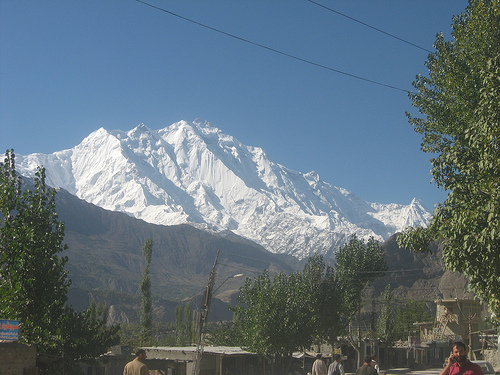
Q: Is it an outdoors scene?
A: Yes, it is outdoors.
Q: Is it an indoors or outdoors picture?
A: It is outdoors.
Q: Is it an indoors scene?
A: No, it is outdoors.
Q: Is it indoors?
A: No, it is outdoors.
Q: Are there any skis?
A: No, there are no skis.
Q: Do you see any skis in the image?
A: No, there are no skis.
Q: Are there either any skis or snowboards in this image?
A: No, there are no skis or snowboards.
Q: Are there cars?
A: No, there are no cars.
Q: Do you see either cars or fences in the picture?
A: No, there are no cars or fences.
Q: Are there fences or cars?
A: No, there are no cars or fences.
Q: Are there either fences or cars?
A: No, there are no cars or fences.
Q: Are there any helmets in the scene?
A: No, there are no helmets.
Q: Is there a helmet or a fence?
A: No, there are no helmets or fences.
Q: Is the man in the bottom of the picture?
A: Yes, the man is in the bottom of the image.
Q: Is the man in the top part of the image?
A: No, the man is in the bottom of the image.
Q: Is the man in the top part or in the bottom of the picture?
A: The man is in the bottom of the image.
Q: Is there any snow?
A: Yes, there is snow.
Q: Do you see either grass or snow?
A: Yes, there is snow.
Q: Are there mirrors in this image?
A: No, there are no mirrors.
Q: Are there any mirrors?
A: No, there are no mirrors.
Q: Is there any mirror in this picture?
A: No, there are no mirrors.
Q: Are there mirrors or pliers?
A: No, there are no mirrors or pliers.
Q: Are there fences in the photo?
A: No, there are no fences.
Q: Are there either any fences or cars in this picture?
A: No, there are no fences or cars.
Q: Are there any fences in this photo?
A: No, there are no fences.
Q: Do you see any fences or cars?
A: No, there are no fences or cars.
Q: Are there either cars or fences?
A: No, there are no fences or cars.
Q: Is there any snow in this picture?
A: Yes, there is snow.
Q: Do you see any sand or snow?
A: Yes, there is snow.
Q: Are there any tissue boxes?
A: No, there are no tissue boxes.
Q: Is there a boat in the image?
A: No, there are no boats.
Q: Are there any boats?
A: No, there are no boats.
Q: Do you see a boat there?
A: No, there are no boats.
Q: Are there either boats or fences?
A: No, there are no boats or fences.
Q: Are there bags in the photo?
A: No, there are no bags.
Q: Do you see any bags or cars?
A: No, there are no bags or cars.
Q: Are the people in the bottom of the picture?
A: Yes, the people are in the bottom of the image.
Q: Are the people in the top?
A: No, the people are in the bottom of the image.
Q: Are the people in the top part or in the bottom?
A: The people are in the bottom of the image.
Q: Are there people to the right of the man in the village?
A: Yes, there are people to the right of the man.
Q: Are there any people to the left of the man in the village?
A: No, the people are to the right of the man.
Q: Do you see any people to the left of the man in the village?
A: No, the people are to the right of the man.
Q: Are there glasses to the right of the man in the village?
A: No, there are people to the right of the man.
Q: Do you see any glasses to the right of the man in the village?
A: No, there are people to the right of the man.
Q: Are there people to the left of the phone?
A: Yes, there are people to the left of the phone.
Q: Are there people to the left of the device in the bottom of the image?
A: Yes, there are people to the left of the phone.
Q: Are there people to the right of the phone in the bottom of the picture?
A: No, the people are to the left of the telephone.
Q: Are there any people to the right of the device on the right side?
A: No, the people are to the left of the telephone.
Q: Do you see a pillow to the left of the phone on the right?
A: No, there are people to the left of the phone.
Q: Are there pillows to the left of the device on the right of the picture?
A: No, there are people to the left of the phone.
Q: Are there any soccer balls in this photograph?
A: No, there are no soccer balls.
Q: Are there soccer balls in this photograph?
A: No, there are no soccer balls.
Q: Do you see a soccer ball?
A: No, there are no soccer balls.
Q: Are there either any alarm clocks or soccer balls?
A: No, there are no soccer balls or alarm clocks.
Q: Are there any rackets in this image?
A: No, there are no rackets.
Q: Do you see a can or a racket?
A: No, there are no rackets or cans.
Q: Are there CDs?
A: No, there are no cds.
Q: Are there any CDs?
A: No, there are no cds.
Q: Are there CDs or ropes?
A: No, there are no CDs or ropes.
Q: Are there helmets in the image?
A: No, there are no helmets.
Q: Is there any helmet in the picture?
A: No, there are no helmets.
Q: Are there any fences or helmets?
A: No, there are no helmets or fences.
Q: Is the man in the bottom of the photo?
A: Yes, the man is in the bottom of the image.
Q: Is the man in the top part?
A: No, the man is in the bottom of the image.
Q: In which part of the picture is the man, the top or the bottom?
A: The man is in the bottom of the image.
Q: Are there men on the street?
A: Yes, there is a man on the street.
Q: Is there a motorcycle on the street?
A: No, there is a man on the street.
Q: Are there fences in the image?
A: No, there are no fences.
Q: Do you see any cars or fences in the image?
A: No, there are no fences or cars.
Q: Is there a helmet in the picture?
A: No, there are no helmets.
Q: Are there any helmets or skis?
A: No, there are no helmets or skis.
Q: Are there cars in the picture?
A: No, there are no cars.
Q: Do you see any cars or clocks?
A: No, there are no cars or clocks.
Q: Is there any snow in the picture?
A: Yes, there is snow.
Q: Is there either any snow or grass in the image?
A: Yes, there is snow.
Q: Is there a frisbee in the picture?
A: No, there are no frisbees.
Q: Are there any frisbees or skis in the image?
A: No, there are no frisbees or skis.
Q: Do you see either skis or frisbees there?
A: No, there are no frisbees or skis.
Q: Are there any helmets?
A: No, there are no helmets.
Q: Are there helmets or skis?
A: No, there are no helmets or skis.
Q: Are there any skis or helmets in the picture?
A: No, there are no helmets or skis.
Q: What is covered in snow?
A: The mountain is covered in snow.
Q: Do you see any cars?
A: No, there are no cars.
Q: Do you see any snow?
A: Yes, there is snow.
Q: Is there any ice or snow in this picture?
A: Yes, there is snow.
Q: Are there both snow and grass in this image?
A: No, there is snow but no grass.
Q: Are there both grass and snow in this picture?
A: No, there is snow but no grass.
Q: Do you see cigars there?
A: No, there are no cigars.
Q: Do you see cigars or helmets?
A: No, there are no cigars or helmets.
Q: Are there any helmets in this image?
A: No, there are no helmets.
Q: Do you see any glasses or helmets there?
A: No, there are no helmets or glasses.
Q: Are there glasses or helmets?
A: No, there are no helmets or glasses.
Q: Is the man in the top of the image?
A: No, the man is in the bottom of the image.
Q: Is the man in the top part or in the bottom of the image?
A: The man is in the bottom of the image.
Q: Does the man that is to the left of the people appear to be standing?
A: Yes, the man is standing.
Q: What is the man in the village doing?
A: The man is standing.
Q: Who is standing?
A: The man is standing.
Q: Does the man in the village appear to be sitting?
A: No, the man is standing.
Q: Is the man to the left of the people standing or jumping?
A: The man is standing.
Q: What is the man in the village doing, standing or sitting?
A: The man is standing.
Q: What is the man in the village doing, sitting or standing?
A: The man is standing.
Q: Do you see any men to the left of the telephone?
A: Yes, there is a man to the left of the telephone.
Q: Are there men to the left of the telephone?
A: Yes, there is a man to the left of the telephone.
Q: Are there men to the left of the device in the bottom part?
A: Yes, there is a man to the left of the telephone.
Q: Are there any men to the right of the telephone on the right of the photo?
A: No, the man is to the left of the telephone.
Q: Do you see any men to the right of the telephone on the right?
A: No, the man is to the left of the telephone.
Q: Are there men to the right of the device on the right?
A: No, the man is to the left of the telephone.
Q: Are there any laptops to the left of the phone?
A: No, there is a man to the left of the phone.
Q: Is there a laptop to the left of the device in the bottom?
A: No, there is a man to the left of the phone.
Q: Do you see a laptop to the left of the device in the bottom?
A: No, there is a man to the left of the phone.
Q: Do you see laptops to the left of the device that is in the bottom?
A: No, there is a man to the left of the phone.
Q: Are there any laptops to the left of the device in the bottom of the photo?
A: No, there is a man to the left of the phone.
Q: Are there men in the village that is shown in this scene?
A: Yes, there is a man in the village.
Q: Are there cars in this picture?
A: No, there are no cars.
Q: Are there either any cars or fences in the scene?
A: No, there are no cars or fences.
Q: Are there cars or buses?
A: No, there are no cars or buses.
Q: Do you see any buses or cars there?
A: No, there are no cars or buses.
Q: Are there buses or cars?
A: No, there are no cars or buses.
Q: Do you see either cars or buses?
A: No, there are no cars or buses.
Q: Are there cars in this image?
A: No, there are no cars.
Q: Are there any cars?
A: No, there are no cars.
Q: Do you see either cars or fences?
A: No, there are no cars or fences.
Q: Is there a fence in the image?
A: No, there are no fences.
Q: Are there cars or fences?
A: No, there are no fences or cars.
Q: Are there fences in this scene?
A: No, there are no fences.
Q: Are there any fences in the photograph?
A: No, there are no fences.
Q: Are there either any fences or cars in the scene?
A: No, there are no fences or cars.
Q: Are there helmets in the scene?
A: No, there are no helmets.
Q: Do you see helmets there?
A: No, there are no helmets.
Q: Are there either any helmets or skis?
A: No, there are no helmets or skis.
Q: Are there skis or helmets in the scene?
A: No, there are no helmets or skis.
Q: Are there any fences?
A: No, there are no fences.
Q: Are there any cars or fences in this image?
A: No, there are no fences or cars.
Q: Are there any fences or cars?
A: No, there are no fences or cars.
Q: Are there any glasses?
A: No, there are no glasses.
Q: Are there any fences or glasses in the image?
A: No, there are no glasses or fences.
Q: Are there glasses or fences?
A: No, there are no glasses or fences.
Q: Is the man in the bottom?
A: Yes, the man is in the bottom of the image.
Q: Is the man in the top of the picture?
A: No, the man is in the bottom of the image.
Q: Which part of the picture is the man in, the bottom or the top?
A: The man is in the bottom of the image.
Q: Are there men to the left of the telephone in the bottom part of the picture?
A: Yes, there is a man to the left of the phone.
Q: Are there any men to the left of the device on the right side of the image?
A: Yes, there is a man to the left of the phone.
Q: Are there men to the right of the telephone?
A: No, the man is to the left of the telephone.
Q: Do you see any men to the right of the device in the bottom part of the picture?
A: No, the man is to the left of the telephone.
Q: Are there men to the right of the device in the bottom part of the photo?
A: No, the man is to the left of the telephone.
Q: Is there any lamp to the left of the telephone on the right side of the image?
A: No, there is a man to the left of the telephone.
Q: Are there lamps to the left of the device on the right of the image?
A: No, there is a man to the left of the telephone.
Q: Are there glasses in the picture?
A: No, there are no glasses.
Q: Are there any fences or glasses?
A: No, there are no glasses or fences.